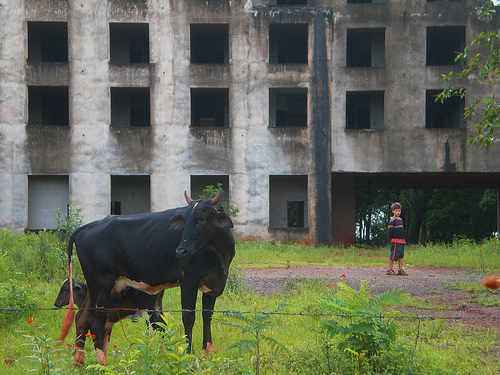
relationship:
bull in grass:
[70, 208, 234, 354] [265, 316, 319, 351]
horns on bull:
[177, 189, 221, 202] [70, 208, 234, 354]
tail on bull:
[60, 234, 72, 318] [70, 208, 234, 354]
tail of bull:
[60, 234, 72, 318] [70, 208, 234, 354]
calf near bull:
[66, 283, 148, 326] [70, 208, 234, 354]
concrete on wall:
[294, 12, 338, 20] [155, 8, 187, 87]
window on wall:
[27, 17, 89, 70] [155, 8, 187, 87]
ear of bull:
[161, 213, 190, 229] [70, 208, 234, 354]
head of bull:
[172, 201, 215, 269] [56, 186, 236, 370]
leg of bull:
[172, 298, 203, 353] [56, 186, 236, 370]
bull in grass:
[56, 186, 236, 370] [265, 316, 319, 351]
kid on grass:
[379, 185, 408, 274] [265, 316, 319, 351]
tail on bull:
[60, 234, 72, 318] [56, 186, 236, 370]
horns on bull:
[177, 189, 221, 202] [56, 186, 236, 370]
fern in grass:
[304, 302, 371, 347] [265, 316, 319, 351]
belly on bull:
[120, 275, 146, 287] [56, 186, 236, 370]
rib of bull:
[130, 226, 161, 239] [56, 186, 236, 370]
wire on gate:
[454, 231, 468, 239] [426, 189, 474, 254]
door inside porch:
[286, 197, 312, 232] [247, 180, 270, 215]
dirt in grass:
[260, 267, 284, 280] [265, 316, 319, 351]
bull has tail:
[56, 186, 236, 370] [60, 234, 72, 318]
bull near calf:
[56, 186, 236, 370] [66, 283, 148, 326]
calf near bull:
[66, 283, 148, 326] [56, 186, 236, 370]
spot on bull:
[186, 201, 203, 208] [56, 186, 236, 370]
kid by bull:
[379, 185, 408, 274] [56, 186, 236, 370]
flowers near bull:
[11, 303, 45, 353] [56, 186, 236, 370]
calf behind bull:
[52, 277, 165, 360] [56, 186, 236, 370]